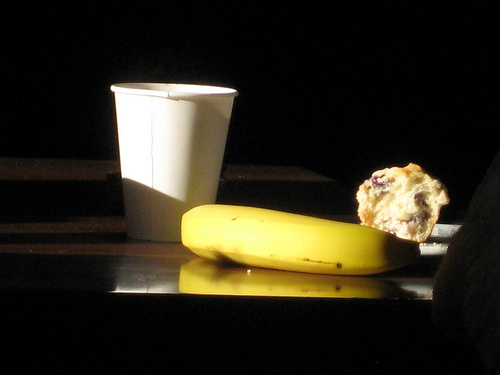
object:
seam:
[147, 138, 156, 240]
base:
[124, 229, 183, 243]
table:
[0, 216, 461, 303]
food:
[354, 163, 448, 245]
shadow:
[119, 177, 189, 243]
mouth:
[108, 82, 238, 101]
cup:
[109, 82, 240, 244]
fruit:
[370, 174, 391, 189]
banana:
[179, 203, 419, 276]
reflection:
[177, 254, 418, 300]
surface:
[0, 219, 460, 302]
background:
[0, 0, 499, 374]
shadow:
[0, 216, 125, 308]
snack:
[354, 161, 450, 243]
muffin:
[353, 163, 449, 244]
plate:
[416, 223, 462, 256]